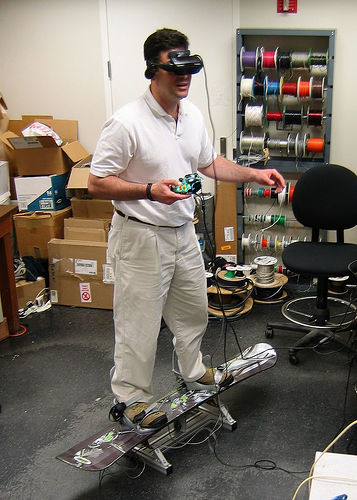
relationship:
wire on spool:
[298, 54, 307, 59] [293, 52, 307, 65]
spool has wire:
[293, 52, 307, 65] [298, 54, 307, 59]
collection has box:
[10, 111, 140, 327] [47, 236, 119, 311]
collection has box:
[10, 111, 140, 327] [61, 214, 114, 242]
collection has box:
[10, 111, 140, 327] [69, 153, 109, 200]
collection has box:
[10, 111, 140, 327] [0, 118, 92, 178]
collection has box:
[10, 111, 140, 327] [12, 173, 72, 213]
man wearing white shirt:
[84, 26, 286, 433] [88, 81, 216, 227]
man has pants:
[84, 26, 286, 433] [106, 211, 209, 406]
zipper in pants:
[170, 228, 184, 266] [101, 210, 233, 427]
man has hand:
[84, 26, 286, 433] [150, 177, 179, 211]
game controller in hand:
[166, 171, 202, 196] [150, 177, 179, 211]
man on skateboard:
[84, 26, 286, 433] [56, 343, 277, 472]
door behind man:
[104, 2, 237, 195] [106, 39, 232, 459]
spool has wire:
[238, 47, 261, 74] [244, 49, 251, 61]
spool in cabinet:
[238, 47, 261, 74] [0, 199, 23, 350]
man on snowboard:
[84, 26, 286, 433] [54, 340, 277, 476]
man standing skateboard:
[35, 10, 281, 440] [56, 343, 277, 472]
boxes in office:
[1, 99, 110, 315] [3, 5, 345, 484]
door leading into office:
[104, 2, 237, 195] [3, 5, 345, 484]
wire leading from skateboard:
[158, 416, 222, 451] [56, 343, 277, 472]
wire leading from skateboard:
[208, 426, 306, 475] [56, 343, 277, 472]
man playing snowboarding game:
[84, 26, 286, 433] [53, 341, 274, 482]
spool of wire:
[294, 76, 315, 100] [301, 81, 308, 95]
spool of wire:
[241, 100, 265, 129] [248, 107, 259, 125]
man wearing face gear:
[84, 26, 286, 433] [144, 46, 203, 79]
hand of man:
[256, 164, 286, 196] [84, 26, 286, 433]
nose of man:
[176, 73, 192, 81] [88, 26, 294, 373]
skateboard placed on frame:
[56, 343, 277, 472] [128, 391, 237, 479]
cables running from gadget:
[98, 55, 356, 487] [46, 341, 283, 466]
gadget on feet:
[46, 341, 283, 466] [108, 393, 169, 433]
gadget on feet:
[46, 341, 283, 466] [177, 360, 236, 392]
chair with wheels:
[266, 155, 345, 364] [273, 325, 324, 369]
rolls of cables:
[238, 40, 328, 283] [240, 46, 318, 241]